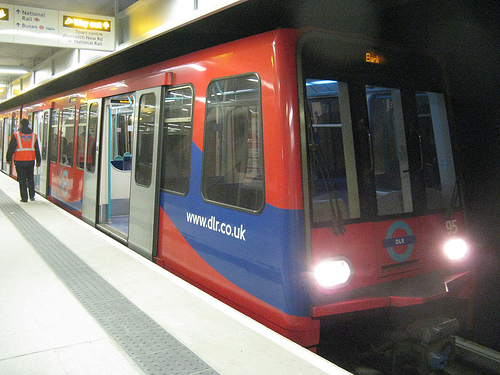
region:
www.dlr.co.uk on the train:
[186, 208, 247, 249]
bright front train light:
[309, 250, 354, 297]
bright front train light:
[440, 233, 470, 267]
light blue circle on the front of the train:
[384, 217, 419, 265]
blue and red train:
[4, 29, 475, 339]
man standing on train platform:
[1, 113, 50, 201]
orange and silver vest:
[8, 128, 40, 160]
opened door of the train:
[95, 91, 157, 232]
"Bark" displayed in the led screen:
[362, 48, 384, 62]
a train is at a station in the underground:
[4, 2, 492, 372]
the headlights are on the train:
[303, 220, 478, 316]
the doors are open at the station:
[4, 85, 160, 254]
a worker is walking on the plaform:
[3, 111, 48, 213]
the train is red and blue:
[3, 17, 483, 371]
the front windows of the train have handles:
[298, 70, 467, 234]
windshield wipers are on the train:
[310, 119, 471, 236]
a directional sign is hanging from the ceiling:
[2, 2, 122, 55]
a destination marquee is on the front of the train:
[302, 35, 449, 76]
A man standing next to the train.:
[16, 114, 56, 224]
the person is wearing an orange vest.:
[1, 128, 46, 160]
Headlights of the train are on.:
[307, 244, 470, 281]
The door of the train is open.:
[73, 98, 178, 240]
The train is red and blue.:
[64, 72, 419, 304]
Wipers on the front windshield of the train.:
[312, 135, 376, 233]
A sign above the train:
[1, 2, 123, 57]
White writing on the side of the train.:
[171, 207, 253, 253]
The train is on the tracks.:
[349, 317, 457, 374]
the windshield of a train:
[293, 28, 468, 233]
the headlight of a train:
[307, 255, 354, 291]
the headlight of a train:
[440, 233, 466, 263]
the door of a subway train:
[90, 93, 159, 260]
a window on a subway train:
[195, 76, 268, 218]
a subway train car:
[0, 27, 477, 359]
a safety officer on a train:
[0, 117, 47, 205]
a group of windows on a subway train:
[34, 67, 283, 223]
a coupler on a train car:
[383, 303, 466, 373]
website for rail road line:
[181, 204, 256, 245]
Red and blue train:
[6, 77, 488, 332]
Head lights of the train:
[308, 227, 480, 289]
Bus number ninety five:
[437, 212, 461, 245]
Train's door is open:
[83, 83, 167, 252]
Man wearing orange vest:
[6, 115, 55, 207]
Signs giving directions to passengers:
[4, 4, 129, 54]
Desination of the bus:
[353, 51, 415, 76]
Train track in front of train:
[442, 319, 498, 374]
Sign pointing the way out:
[63, 8, 122, 34]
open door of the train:
[86, 105, 160, 230]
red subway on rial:
[26, 94, 332, 247]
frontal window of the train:
[306, 44, 462, 206]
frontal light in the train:
[310, 233, 492, 290]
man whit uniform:
[17, 108, 47, 205]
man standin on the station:
[10, 113, 40, 186]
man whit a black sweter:
[10, 118, 45, 162]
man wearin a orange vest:
[13, 119, 45, 166]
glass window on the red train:
[297, 70, 353, 220]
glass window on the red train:
[413, 88, 459, 210]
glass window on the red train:
[201, 75, 263, 211]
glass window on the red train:
[160, 86, 190, 197]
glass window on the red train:
[133, 92, 154, 188]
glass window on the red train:
[72, 97, 87, 164]